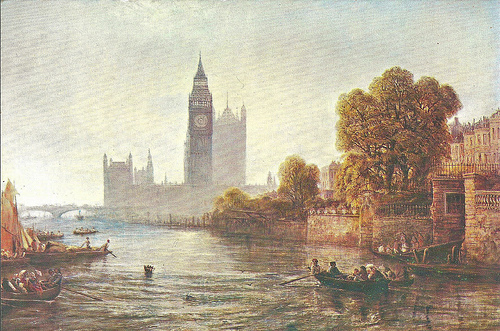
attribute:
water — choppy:
[0, 217, 498, 327]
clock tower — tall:
[186, 48, 213, 204]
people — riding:
[346, 261, 395, 281]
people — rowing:
[310, 259, 390, 284]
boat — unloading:
[366, 227, 470, 281]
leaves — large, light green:
[395, 112, 420, 154]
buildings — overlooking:
[424, 111, 497, 182]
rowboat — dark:
[312, 270, 396, 295]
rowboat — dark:
[392, 272, 416, 287]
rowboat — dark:
[0, 275, 65, 305]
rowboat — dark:
[13, 243, 114, 263]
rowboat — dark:
[72, 225, 100, 236]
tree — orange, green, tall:
[333, 53, 461, 226]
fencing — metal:
[440, 159, 499, 176]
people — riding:
[291, 247, 403, 303]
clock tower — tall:
[185, 50, 214, 188]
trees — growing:
[327, 61, 465, 216]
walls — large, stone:
[209, 170, 476, 268]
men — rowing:
[295, 254, 393, 275]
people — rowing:
[9, 256, 77, 283]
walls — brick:
[227, 216, 371, 245]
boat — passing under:
[30, 223, 111, 245]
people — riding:
[320, 261, 400, 292]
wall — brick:
[231, 174, 498, 260]